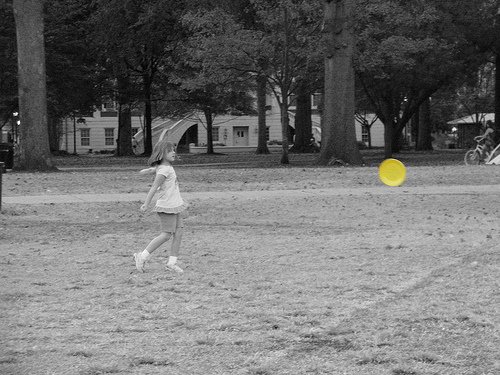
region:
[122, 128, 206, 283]
A young girl in the foreground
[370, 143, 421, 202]
A flying disc in the foreground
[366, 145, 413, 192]
The flying disc is yellow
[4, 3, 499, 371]
Photo was taken in black and white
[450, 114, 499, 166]
A person in the background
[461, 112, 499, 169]
Person is on a bike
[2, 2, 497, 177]
Tall trees in the background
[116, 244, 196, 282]
Young girl is wearing tennis shoes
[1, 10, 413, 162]
A white building in the background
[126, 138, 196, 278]
young girl in a field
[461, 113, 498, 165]
child on a bike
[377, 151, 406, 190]
yellow dot in the picture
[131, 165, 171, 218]
outstretched right arm of girl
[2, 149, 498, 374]
large grassy field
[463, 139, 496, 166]
bicycle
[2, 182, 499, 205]
sidewalk in a park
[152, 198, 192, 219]
ruffles on a girl's shirt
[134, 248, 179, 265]
pair of white colored girl's socks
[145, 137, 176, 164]
girl's medium length hair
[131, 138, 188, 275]
A little girl standing in the grass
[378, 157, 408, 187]
A Frisbee in midair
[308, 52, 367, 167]
A thick trunk of a tree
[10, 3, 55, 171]
A trunk of a tree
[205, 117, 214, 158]
Trunk of a thin tree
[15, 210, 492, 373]
Grass in a large field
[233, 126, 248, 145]
Double door of a house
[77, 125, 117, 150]
Windows on the front of a house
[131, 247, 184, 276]
Light shoes on the grass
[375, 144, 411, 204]
yellow frisbee in air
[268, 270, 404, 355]
ground has clumpy grass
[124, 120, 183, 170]
girl has dark hair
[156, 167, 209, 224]
girl has light shirt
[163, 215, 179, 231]
girl is wearing shorts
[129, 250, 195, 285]
girl has white socks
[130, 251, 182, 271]
girl has white shoes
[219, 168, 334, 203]
grey path behind girl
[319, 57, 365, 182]
thick dark tree trunk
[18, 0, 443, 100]
forest of trees behind girl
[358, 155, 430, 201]
yellow disc flying in air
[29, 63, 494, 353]
picture is in black and white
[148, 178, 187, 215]
girl in light colored shirt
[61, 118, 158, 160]
white building in background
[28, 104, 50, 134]
very large tree trunk in back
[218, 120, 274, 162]
double white doors on building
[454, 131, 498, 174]
person riding bike in distance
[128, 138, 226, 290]
girl tossed yellow disc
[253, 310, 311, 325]
grass in playing area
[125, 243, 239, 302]
girl in light colored shoes